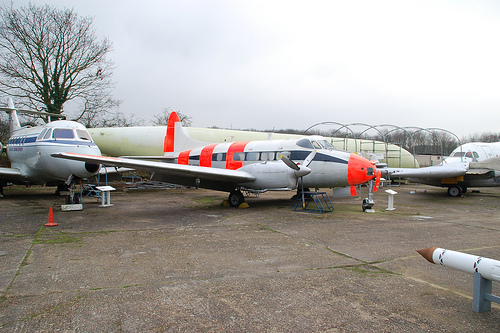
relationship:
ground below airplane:
[0, 169, 500, 331] [0, 94, 134, 205]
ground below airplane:
[0, 169, 500, 331] [49, 107, 381, 208]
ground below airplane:
[0, 169, 500, 331] [435, 139, 497, 179]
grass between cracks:
[28, 226, 76, 247] [0, 228, 53, 308]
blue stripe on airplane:
[5, 130, 37, 152] [0, 97, 140, 209]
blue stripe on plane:
[5, 130, 37, 152] [45, 136, 379, 208]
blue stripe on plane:
[5, 130, 37, 152] [380, 132, 498, 199]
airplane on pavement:
[49, 109, 390, 213] [26, 208, 420, 298]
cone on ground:
[44, 202, 58, 232] [85, 213, 405, 321]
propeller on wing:
[288, 150, 323, 209] [50, 142, 254, 190]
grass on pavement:
[28, 226, 76, 247] [0, 180, 497, 332]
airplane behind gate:
[49, 109, 390, 213] [11, 110, 470, 183]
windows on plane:
[199, 149, 294, 164] [47, 107, 427, 212]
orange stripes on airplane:
[179, 140, 249, 169] [49, 109, 390, 213]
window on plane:
[217, 155, 227, 166] [112, 131, 394, 211]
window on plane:
[231, 147, 248, 161] [112, 131, 394, 211]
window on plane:
[244, 145, 264, 160] [112, 131, 394, 211]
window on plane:
[261, 145, 278, 160] [112, 131, 394, 211]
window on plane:
[278, 147, 292, 162] [112, 131, 394, 211]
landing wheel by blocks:
[226, 190, 243, 206] [218, 198, 250, 209]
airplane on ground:
[435, 139, 497, 179] [0, 202, 499, 331]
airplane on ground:
[49, 135, 384, 210] [0, 202, 499, 331]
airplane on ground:
[0, 95, 136, 195] [0, 202, 499, 331]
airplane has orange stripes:
[49, 109, 390, 213] [179, 140, 249, 166]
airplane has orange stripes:
[49, 109, 390, 213] [162, 109, 179, 151]